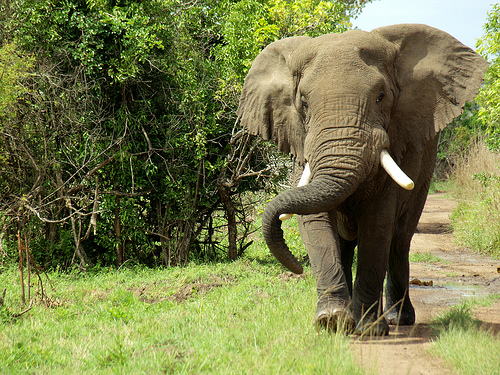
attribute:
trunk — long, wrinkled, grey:
[246, 154, 372, 282]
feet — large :
[311, 287, 425, 334]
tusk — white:
[375, 148, 414, 189]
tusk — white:
[295, 155, 310, 187]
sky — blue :
[347, 1, 497, 53]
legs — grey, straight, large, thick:
[298, 207, 424, 342]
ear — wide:
[217, 26, 324, 158]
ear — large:
[392, 24, 489, 145]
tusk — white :
[348, 147, 428, 195]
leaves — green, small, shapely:
[107, 23, 149, 82]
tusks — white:
[283, 149, 416, 191]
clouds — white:
[345, 1, 497, 63]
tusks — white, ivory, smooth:
[276, 143, 418, 202]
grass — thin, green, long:
[193, 303, 307, 366]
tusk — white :
[357, 139, 419, 196]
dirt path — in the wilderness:
[357, 182, 498, 372]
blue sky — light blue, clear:
[365, 7, 473, 20]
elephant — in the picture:
[234, 22, 492, 338]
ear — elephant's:
[385, 20, 491, 137]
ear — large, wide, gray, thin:
[371, 21, 487, 165]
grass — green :
[76, 292, 262, 370]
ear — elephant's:
[234, 35, 295, 145]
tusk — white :
[376, 146, 411, 190]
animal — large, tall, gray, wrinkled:
[225, 24, 492, 349]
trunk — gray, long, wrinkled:
[262, 141, 380, 274]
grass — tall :
[303, 300, 370, 367]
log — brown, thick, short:
[414, 223, 455, 234]